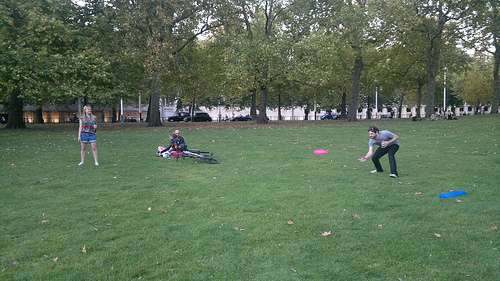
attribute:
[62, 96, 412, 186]
people — some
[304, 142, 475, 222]
frisbees — some, flying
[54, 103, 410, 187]
people — some, standing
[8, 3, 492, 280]
day — off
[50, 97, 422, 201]
people — out, some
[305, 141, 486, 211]
discs — flying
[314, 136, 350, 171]
frisbee — pink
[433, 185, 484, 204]
disc — blue, flying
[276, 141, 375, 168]
frisbee — thrown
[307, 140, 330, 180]
frisbee — red, in motion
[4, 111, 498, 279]
field — green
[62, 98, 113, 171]
girl — young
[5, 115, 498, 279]
grass — green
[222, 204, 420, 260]
leaves — some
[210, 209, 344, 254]
patch — big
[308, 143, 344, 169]
frisbee — small, pink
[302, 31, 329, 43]
leaves — bunch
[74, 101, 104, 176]
woman — standing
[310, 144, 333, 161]
frisbee — airborne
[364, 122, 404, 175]
man — bending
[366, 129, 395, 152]
shirt — gray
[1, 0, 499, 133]
trees — tall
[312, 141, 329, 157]
frisbee — red, airborne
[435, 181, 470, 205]
frisbee — airborne, blue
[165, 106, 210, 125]
car — parked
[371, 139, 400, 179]
pants — long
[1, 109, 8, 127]
dumpster — garbage receptacle